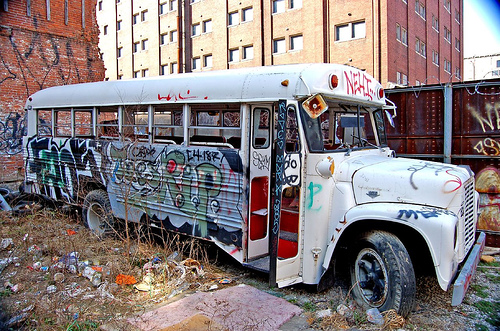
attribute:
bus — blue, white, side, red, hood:
[29, 41, 425, 256]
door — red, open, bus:
[236, 175, 314, 267]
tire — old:
[342, 211, 425, 317]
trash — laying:
[18, 219, 200, 321]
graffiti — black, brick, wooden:
[2, 17, 96, 94]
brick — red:
[49, 5, 86, 34]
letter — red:
[319, 68, 378, 98]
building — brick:
[252, 32, 402, 64]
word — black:
[157, 157, 250, 227]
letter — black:
[176, 147, 235, 164]